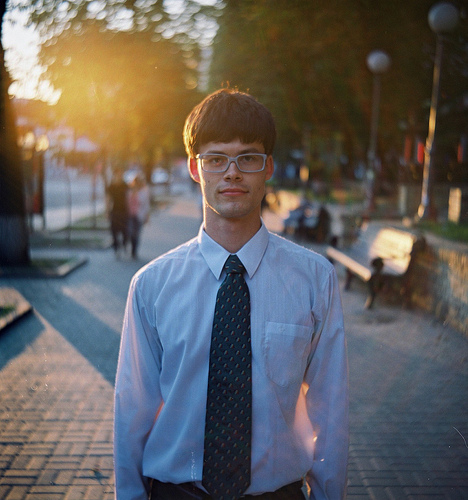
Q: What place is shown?
A: It is a park.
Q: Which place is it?
A: It is a park.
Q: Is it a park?
A: Yes, it is a park.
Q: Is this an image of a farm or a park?
A: It is showing a park.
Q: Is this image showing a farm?
A: No, the picture is showing a park.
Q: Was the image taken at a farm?
A: No, the picture was taken in a park.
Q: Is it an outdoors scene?
A: Yes, it is outdoors.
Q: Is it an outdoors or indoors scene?
A: It is outdoors.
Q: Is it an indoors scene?
A: No, it is outdoors.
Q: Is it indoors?
A: No, it is outdoors.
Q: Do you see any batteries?
A: No, there are no batteries.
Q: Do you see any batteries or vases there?
A: No, there are no batteries or vases.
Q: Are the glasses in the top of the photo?
A: Yes, the glasses are in the top of the image.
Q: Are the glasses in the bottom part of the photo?
A: No, the glasses are in the top of the image.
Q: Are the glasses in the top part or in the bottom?
A: The glasses are in the top of the image.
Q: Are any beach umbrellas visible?
A: No, there are no beach umbrellas.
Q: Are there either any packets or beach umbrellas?
A: No, there are no beach umbrellas or packets.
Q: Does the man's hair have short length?
A: Yes, the hair is short.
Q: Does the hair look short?
A: Yes, the hair is short.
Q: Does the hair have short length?
A: Yes, the hair is short.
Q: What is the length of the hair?
A: The hair is short.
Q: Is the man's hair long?
A: No, the hair is short.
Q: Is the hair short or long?
A: The hair is short.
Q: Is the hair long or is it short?
A: The hair is short.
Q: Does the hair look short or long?
A: The hair is short.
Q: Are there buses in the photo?
A: No, there are no buses.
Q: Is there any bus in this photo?
A: No, there are no buses.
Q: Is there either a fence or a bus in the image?
A: No, there are no buses or fences.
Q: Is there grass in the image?
A: Yes, there is grass.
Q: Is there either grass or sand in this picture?
A: Yes, there is grass.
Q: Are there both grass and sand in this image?
A: No, there is grass but no sand.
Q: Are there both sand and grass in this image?
A: No, there is grass but no sand.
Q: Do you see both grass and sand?
A: No, there is grass but no sand.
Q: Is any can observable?
A: No, there are no cans.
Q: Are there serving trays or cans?
A: No, there are no cans or serving trays.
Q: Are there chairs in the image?
A: No, there are no chairs.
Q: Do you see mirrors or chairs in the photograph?
A: No, there are no chairs or mirrors.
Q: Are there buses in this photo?
A: No, there are no buses.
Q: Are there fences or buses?
A: No, there are no buses or fences.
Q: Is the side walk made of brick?
A: Yes, the side walk is made of brick.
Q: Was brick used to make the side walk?
A: Yes, the side walk is made of brick.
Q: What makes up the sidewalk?
A: The sidewalk is made of brick.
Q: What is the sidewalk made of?
A: The sidewalk is made of brick.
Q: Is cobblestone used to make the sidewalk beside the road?
A: No, the sidewalk is made of brick.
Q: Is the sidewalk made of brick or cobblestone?
A: The sidewalk is made of brick.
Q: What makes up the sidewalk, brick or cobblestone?
A: The sidewalk is made of brick.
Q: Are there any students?
A: No, there are no students.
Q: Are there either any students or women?
A: No, there are no students or women.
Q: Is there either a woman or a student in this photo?
A: No, there are no students or women.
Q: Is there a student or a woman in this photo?
A: No, there are no students or women.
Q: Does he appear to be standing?
A: Yes, the man is standing.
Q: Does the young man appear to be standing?
A: Yes, the man is standing.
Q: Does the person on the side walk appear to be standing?
A: Yes, the man is standing.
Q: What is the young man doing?
A: The man is standing.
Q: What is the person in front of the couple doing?
A: The man is standing.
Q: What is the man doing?
A: The man is standing.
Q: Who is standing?
A: The man is standing.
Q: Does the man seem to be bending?
A: No, the man is standing.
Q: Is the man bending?
A: No, the man is standing.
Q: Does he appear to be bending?
A: No, the man is standing.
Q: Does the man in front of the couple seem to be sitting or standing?
A: The man is standing.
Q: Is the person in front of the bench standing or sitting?
A: The man is standing.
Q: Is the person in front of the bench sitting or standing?
A: The man is standing.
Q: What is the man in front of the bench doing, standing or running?
A: The man is standing.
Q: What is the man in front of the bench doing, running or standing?
A: The man is standing.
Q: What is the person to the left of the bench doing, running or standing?
A: The man is standing.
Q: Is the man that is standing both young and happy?
A: Yes, the man is young and happy.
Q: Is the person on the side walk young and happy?
A: Yes, the man is young and happy.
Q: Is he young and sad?
A: No, the man is young but happy.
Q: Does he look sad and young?
A: No, the man is young but happy.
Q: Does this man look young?
A: Yes, the man is young.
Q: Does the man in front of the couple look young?
A: Yes, the man is young.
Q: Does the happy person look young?
A: Yes, the man is young.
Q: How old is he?
A: The man is young.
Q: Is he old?
A: No, the man is young.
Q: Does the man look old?
A: No, the man is young.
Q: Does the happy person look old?
A: No, the man is young.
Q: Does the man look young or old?
A: The man is young.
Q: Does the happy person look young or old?
A: The man is young.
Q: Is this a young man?
A: Yes, this is a young man.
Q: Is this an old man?
A: No, this is a young man.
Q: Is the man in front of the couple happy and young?
A: Yes, the man is happy and young.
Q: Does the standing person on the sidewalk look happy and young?
A: Yes, the man is happy and young.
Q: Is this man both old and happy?
A: No, the man is happy but young.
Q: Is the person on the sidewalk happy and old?
A: No, the man is happy but young.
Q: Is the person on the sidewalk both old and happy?
A: No, the man is happy but young.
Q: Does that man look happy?
A: Yes, the man is happy.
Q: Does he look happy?
A: Yes, the man is happy.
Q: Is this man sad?
A: No, the man is happy.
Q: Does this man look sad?
A: No, the man is happy.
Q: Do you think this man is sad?
A: No, the man is happy.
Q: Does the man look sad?
A: No, the man is happy.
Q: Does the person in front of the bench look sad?
A: No, the man is happy.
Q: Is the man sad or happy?
A: The man is happy.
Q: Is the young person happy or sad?
A: The man is happy.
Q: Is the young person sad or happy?
A: The man is happy.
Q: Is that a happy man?
A: Yes, that is a happy man.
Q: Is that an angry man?
A: No, that is a happy man.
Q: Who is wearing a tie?
A: The man is wearing a tie.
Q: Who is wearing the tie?
A: The man is wearing a tie.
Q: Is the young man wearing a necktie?
A: Yes, the man is wearing a necktie.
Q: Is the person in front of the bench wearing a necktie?
A: Yes, the man is wearing a necktie.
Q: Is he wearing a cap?
A: No, the man is wearing a necktie.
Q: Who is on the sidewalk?
A: The man is on the sidewalk.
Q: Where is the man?
A: The man is on the sidewalk.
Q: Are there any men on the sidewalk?
A: Yes, there is a man on the sidewalk.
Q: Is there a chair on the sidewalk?
A: No, there is a man on the sidewalk.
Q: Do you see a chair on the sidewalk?
A: No, there is a man on the sidewalk.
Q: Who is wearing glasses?
A: The man is wearing glasses.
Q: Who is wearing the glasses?
A: The man is wearing glasses.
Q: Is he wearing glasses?
A: Yes, the man is wearing glasses.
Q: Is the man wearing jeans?
A: No, the man is wearing glasses.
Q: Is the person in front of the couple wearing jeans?
A: No, the man is wearing glasses.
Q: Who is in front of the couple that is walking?
A: The man is in front of the couple.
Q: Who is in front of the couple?
A: The man is in front of the couple.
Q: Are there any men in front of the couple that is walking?
A: Yes, there is a man in front of the couple.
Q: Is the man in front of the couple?
A: Yes, the man is in front of the couple.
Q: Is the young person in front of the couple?
A: Yes, the man is in front of the couple.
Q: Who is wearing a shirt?
A: The man is wearing a shirt.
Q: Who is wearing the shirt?
A: The man is wearing a shirt.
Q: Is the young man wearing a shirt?
A: Yes, the man is wearing a shirt.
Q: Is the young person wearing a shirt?
A: Yes, the man is wearing a shirt.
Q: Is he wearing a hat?
A: No, the man is wearing a shirt.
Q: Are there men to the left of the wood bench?
A: Yes, there is a man to the left of the bench.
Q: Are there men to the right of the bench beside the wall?
A: No, the man is to the left of the bench.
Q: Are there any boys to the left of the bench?
A: No, there is a man to the left of the bench.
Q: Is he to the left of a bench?
A: Yes, the man is to the left of a bench.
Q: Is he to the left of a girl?
A: No, the man is to the left of a bench.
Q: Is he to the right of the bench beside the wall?
A: No, the man is to the left of the bench.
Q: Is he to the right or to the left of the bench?
A: The man is to the left of the bench.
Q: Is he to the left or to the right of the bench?
A: The man is to the left of the bench.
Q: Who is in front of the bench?
A: The man is in front of the bench.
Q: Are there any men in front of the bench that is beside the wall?
A: Yes, there is a man in front of the bench.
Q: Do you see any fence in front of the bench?
A: No, there is a man in front of the bench.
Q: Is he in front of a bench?
A: Yes, the man is in front of a bench.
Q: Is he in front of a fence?
A: No, the man is in front of a bench.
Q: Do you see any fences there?
A: No, there are no fences.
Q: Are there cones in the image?
A: No, there are no cones.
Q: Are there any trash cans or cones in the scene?
A: No, there are no cones or trash cans.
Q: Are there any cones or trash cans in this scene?
A: No, there are no cones or trash cans.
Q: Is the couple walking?
A: Yes, the couple is walking.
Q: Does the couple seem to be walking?
A: Yes, the couple is walking.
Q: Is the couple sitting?
A: No, the couple is walking.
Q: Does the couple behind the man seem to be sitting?
A: No, the couple is walking.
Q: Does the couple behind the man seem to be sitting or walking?
A: The couple is walking.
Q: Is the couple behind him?
A: Yes, the couple is behind the man.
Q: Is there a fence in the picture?
A: No, there are no fences.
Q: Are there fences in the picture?
A: No, there are no fences.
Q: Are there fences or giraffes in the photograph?
A: No, there are no fences or giraffes.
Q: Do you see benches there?
A: Yes, there is a bench.